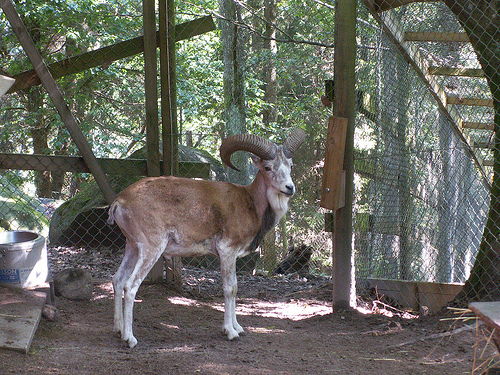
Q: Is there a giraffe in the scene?
A: No, there are no giraffes.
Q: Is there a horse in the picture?
A: No, there are no horses.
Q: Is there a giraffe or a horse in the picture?
A: No, there are no horses or giraffes.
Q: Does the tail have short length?
A: Yes, the tail is short.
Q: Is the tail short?
A: Yes, the tail is short.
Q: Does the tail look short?
A: Yes, the tail is short.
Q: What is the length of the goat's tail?
A: The tail is short.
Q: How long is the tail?
A: The tail is short.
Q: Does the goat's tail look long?
A: No, the tail is short.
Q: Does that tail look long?
A: No, the tail is short.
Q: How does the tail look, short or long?
A: The tail is short.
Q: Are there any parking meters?
A: No, there are no parking meters.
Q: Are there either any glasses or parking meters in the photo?
A: No, there are no parking meters or glasses.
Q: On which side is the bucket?
A: The bucket is on the left of the image.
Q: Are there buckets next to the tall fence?
A: Yes, there is a bucket next to the fence.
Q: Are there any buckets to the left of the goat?
A: Yes, there is a bucket to the left of the goat.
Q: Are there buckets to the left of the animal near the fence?
A: Yes, there is a bucket to the left of the goat.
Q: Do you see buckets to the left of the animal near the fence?
A: Yes, there is a bucket to the left of the goat.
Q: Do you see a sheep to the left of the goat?
A: No, there is a bucket to the left of the goat.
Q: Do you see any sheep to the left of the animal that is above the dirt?
A: No, there is a bucket to the left of the goat.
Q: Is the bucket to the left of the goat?
A: Yes, the bucket is to the left of the goat.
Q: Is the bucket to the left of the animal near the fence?
A: Yes, the bucket is to the left of the goat.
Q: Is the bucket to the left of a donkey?
A: No, the bucket is to the left of the goat.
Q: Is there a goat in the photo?
A: Yes, there is a goat.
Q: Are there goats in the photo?
A: Yes, there is a goat.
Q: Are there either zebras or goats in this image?
A: Yes, there is a goat.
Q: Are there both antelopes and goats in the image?
A: No, there is a goat but no antelopes.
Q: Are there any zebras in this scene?
A: No, there are no zebras.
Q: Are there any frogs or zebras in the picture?
A: No, there are no zebras or frogs.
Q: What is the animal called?
A: The animal is a goat.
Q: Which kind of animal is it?
A: The animal is a goat.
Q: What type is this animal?
A: That is a goat.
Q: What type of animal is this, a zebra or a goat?
A: That is a goat.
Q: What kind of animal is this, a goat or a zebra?
A: That is a goat.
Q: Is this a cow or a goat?
A: This is a goat.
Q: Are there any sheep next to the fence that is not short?
A: No, there is a goat next to the fence.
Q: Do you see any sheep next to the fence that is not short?
A: No, there is a goat next to the fence.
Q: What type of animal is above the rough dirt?
A: The animal is a goat.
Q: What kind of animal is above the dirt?
A: The animal is a goat.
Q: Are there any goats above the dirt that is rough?
A: Yes, there is a goat above the dirt.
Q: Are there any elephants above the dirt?
A: No, there is a goat above the dirt.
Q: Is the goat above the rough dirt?
A: Yes, the goat is above the dirt.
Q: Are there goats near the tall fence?
A: Yes, there is a goat near the fence.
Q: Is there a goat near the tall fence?
A: Yes, there is a goat near the fence.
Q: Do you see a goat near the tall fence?
A: Yes, there is a goat near the fence.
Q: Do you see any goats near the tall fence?
A: Yes, there is a goat near the fence.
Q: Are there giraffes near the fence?
A: No, there is a goat near the fence.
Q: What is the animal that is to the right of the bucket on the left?
A: The animal is a goat.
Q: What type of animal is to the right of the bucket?
A: The animal is a goat.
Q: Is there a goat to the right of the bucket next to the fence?
A: Yes, there is a goat to the right of the bucket.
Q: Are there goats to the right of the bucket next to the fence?
A: Yes, there is a goat to the right of the bucket.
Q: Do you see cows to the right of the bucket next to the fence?
A: No, there is a goat to the right of the bucket.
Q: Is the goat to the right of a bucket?
A: Yes, the goat is to the right of a bucket.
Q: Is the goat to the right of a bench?
A: No, the goat is to the right of a bucket.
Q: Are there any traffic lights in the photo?
A: No, there are no traffic lights.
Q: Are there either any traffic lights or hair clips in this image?
A: No, there are no traffic lights or hair clips.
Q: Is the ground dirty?
A: Yes, the ground is dirty.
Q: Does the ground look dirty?
A: Yes, the ground is dirty.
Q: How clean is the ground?
A: The ground is dirty.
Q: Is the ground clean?
A: No, the ground is dirty.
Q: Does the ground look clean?
A: No, the ground is dirty.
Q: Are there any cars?
A: No, there are no cars.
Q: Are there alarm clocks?
A: No, there are no alarm clocks.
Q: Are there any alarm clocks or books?
A: No, there are no alarm clocks or books.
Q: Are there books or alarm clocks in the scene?
A: No, there are no alarm clocks or books.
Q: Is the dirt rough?
A: Yes, the dirt is rough.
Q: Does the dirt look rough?
A: Yes, the dirt is rough.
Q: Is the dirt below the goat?
A: Yes, the dirt is below the goat.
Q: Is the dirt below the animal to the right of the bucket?
A: Yes, the dirt is below the goat.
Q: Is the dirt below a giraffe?
A: No, the dirt is below the goat.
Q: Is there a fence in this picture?
A: Yes, there is a fence.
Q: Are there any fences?
A: Yes, there is a fence.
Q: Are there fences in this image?
A: Yes, there is a fence.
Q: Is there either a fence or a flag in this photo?
A: Yes, there is a fence.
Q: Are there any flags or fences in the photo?
A: Yes, there is a fence.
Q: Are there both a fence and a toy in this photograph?
A: No, there is a fence but no toys.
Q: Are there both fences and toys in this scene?
A: No, there is a fence but no toys.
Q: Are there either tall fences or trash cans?
A: Yes, there is a tall fence.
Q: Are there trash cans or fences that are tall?
A: Yes, the fence is tall.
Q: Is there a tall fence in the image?
A: Yes, there is a tall fence.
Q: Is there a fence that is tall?
A: Yes, there is a fence that is tall.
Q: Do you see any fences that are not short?
A: Yes, there is a tall fence.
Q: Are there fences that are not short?
A: Yes, there is a tall fence.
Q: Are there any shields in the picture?
A: No, there are no shields.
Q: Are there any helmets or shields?
A: No, there are no shields or helmets.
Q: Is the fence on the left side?
A: Yes, the fence is on the left of the image.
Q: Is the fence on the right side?
A: No, the fence is on the left of the image.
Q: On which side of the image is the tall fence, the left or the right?
A: The fence is on the left of the image.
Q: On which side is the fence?
A: The fence is on the left of the image.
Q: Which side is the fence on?
A: The fence is on the left of the image.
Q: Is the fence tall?
A: Yes, the fence is tall.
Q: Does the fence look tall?
A: Yes, the fence is tall.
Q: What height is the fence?
A: The fence is tall.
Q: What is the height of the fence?
A: The fence is tall.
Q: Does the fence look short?
A: No, the fence is tall.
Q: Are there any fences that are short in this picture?
A: No, there is a fence but it is tall.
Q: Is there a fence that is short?
A: No, there is a fence but it is tall.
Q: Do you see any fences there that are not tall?
A: No, there is a fence but it is tall.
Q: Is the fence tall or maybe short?
A: The fence is tall.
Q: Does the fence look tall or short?
A: The fence is tall.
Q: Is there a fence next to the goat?
A: Yes, there is a fence next to the goat.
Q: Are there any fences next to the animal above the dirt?
A: Yes, there is a fence next to the goat.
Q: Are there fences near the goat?
A: Yes, there is a fence near the goat.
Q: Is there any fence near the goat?
A: Yes, there is a fence near the goat.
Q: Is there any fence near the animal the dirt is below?
A: Yes, there is a fence near the goat.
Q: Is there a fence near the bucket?
A: Yes, there is a fence near the bucket.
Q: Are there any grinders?
A: No, there are no grinders.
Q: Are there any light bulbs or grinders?
A: No, there are no grinders or light bulbs.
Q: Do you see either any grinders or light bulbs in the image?
A: No, there are no grinders or light bulbs.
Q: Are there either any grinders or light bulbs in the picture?
A: No, there are no grinders or light bulbs.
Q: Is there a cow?
A: No, there are no cows.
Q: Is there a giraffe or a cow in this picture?
A: No, there are no cows or giraffes.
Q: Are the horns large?
A: Yes, the horns are large.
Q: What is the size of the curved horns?
A: The horns are large.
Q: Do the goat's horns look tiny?
A: No, the horns are large.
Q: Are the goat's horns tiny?
A: No, the horns are large.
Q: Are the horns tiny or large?
A: The horns are large.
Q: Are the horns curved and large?
A: Yes, the horns are curved and large.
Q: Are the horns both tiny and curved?
A: No, the horns are curved but large.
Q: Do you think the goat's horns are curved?
A: Yes, the horns are curved.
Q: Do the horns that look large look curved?
A: Yes, the horns are curved.